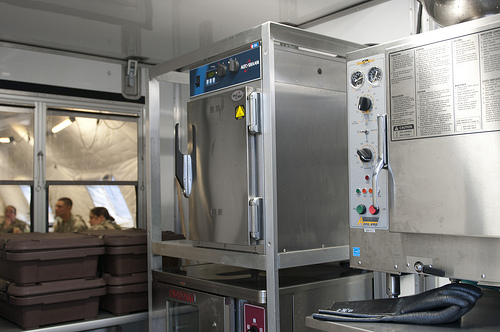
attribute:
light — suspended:
[36, 101, 116, 154]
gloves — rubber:
[355, 276, 480, 318]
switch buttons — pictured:
[345, 55, 381, 237]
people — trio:
[1, 190, 131, 239]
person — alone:
[4, 205, 25, 233]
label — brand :
[173, 44, 263, 93]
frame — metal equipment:
[142, 20, 375, 329]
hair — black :
[90, 201, 118, 225]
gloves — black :
[69, 217, 149, 327]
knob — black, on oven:
[360, 95, 379, 116]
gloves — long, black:
[335, 283, 482, 328]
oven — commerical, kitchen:
[147, 52, 335, 253]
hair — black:
[82, 192, 120, 221]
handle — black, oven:
[156, 124, 219, 224]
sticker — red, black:
[233, 102, 255, 128]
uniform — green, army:
[48, 218, 103, 234]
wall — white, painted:
[27, 37, 101, 87]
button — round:
[367, 199, 396, 223]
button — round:
[226, 58, 242, 76]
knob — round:
[210, 60, 228, 80]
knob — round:
[210, 63, 223, 86]